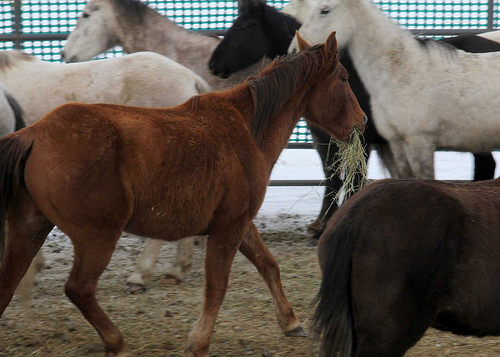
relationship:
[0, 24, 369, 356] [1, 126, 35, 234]
horse has tail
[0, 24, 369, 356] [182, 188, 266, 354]
horse has right leg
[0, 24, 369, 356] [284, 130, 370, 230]
horse carrying grass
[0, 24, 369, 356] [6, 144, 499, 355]
horse are on ground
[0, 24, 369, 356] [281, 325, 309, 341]
horse has hoof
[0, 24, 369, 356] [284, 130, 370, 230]
horse eating grass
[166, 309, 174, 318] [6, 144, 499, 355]
rocks on ground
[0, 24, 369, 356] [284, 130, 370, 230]
horse has grass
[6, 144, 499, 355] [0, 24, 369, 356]
ground beneath horse